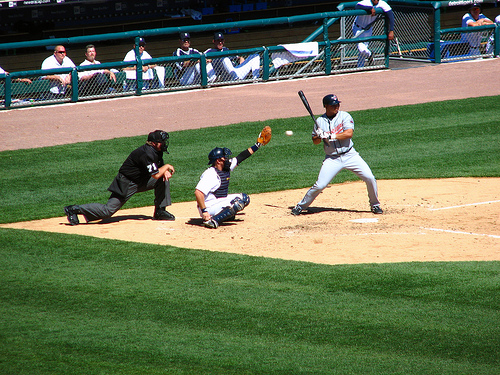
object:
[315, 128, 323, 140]
hand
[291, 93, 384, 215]
batter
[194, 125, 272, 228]
catcher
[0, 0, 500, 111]
dugout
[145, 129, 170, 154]
head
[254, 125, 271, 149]
hand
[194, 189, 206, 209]
arm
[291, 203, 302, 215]
foot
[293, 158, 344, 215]
leg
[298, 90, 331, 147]
bat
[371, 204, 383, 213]
shoes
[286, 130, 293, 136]
ball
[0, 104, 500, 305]
floor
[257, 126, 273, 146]
brown catcher's mitt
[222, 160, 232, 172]
black catcher's mask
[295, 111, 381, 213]
light grey uniform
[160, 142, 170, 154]
black mask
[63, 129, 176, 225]
an umpire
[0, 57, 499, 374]
baseball field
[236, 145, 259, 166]
arm of a man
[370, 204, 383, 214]
foot of a man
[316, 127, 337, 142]
baseball glove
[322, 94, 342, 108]
wearing a hat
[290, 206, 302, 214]
man wearing shoes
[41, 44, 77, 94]
people watching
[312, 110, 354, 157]
grey outfit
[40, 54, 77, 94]
shirts are white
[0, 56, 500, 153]
floor is brown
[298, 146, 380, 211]
pants are white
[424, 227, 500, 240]
white stripes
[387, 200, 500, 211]
white stripes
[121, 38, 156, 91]
this is a person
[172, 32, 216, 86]
this is a person